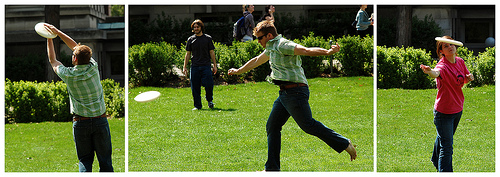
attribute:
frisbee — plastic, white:
[36, 22, 60, 42]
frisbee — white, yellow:
[433, 37, 469, 50]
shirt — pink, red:
[436, 59, 472, 113]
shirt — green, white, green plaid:
[261, 39, 309, 86]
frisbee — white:
[133, 90, 161, 102]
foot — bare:
[346, 140, 362, 164]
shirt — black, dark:
[183, 36, 216, 69]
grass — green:
[132, 102, 263, 169]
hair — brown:
[192, 20, 209, 27]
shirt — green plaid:
[61, 62, 111, 121]